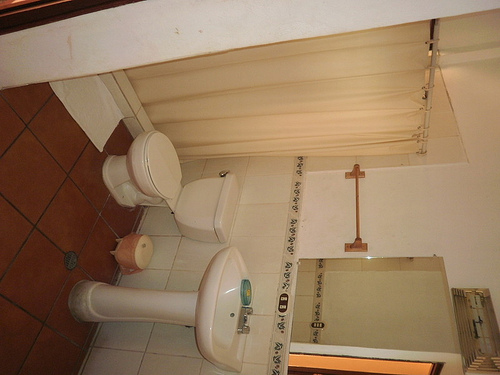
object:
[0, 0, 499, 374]
bathroom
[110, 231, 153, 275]
basket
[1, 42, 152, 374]
floor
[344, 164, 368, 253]
rack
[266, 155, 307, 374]
trim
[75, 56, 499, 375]
wall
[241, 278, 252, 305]
item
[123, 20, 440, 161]
shower curtain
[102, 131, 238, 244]
toilet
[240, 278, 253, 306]
sopdish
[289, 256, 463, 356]
mirror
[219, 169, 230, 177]
handle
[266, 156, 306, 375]
wall ppaper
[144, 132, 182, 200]
seat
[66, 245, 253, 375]
sink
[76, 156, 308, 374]
wall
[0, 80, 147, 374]
tiled floor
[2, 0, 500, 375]
room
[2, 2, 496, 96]
wall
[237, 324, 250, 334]
handle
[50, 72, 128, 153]
towel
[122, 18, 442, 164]
shower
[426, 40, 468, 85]
light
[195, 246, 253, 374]
sink